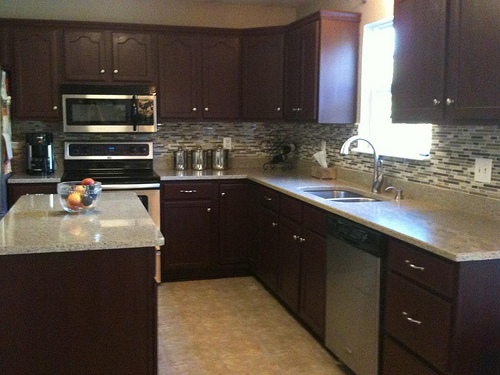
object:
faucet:
[338, 131, 388, 194]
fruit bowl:
[55, 178, 104, 215]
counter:
[0, 190, 167, 255]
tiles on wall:
[169, 135, 183, 139]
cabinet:
[3, 15, 357, 123]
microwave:
[58, 94, 162, 135]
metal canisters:
[171, 145, 190, 171]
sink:
[298, 183, 389, 208]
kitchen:
[0, 0, 500, 374]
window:
[352, 4, 431, 162]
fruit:
[75, 183, 87, 191]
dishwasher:
[318, 228, 386, 375]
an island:
[0, 185, 167, 373]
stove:
[60, 139, 163, 195]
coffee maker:
[22, 128, 57, 177]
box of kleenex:
[309, 162, 337, 181]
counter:
[157, 166, 499, 263]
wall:
[297, 100, 499, 217]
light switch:
[470, 155, 493, 185]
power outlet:
[222, 136, 234, 151]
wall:
[10, 119, 316, 168]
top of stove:
[65, 161, 161, 176]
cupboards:
[385, 0, 500, 124]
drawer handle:
[178, 188, 199, 194]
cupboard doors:
[61, 24, 114, 86]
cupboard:
[249, 187, 459, 375]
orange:
[68, 192, 81, 208]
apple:
[80, 176, 96, 186]